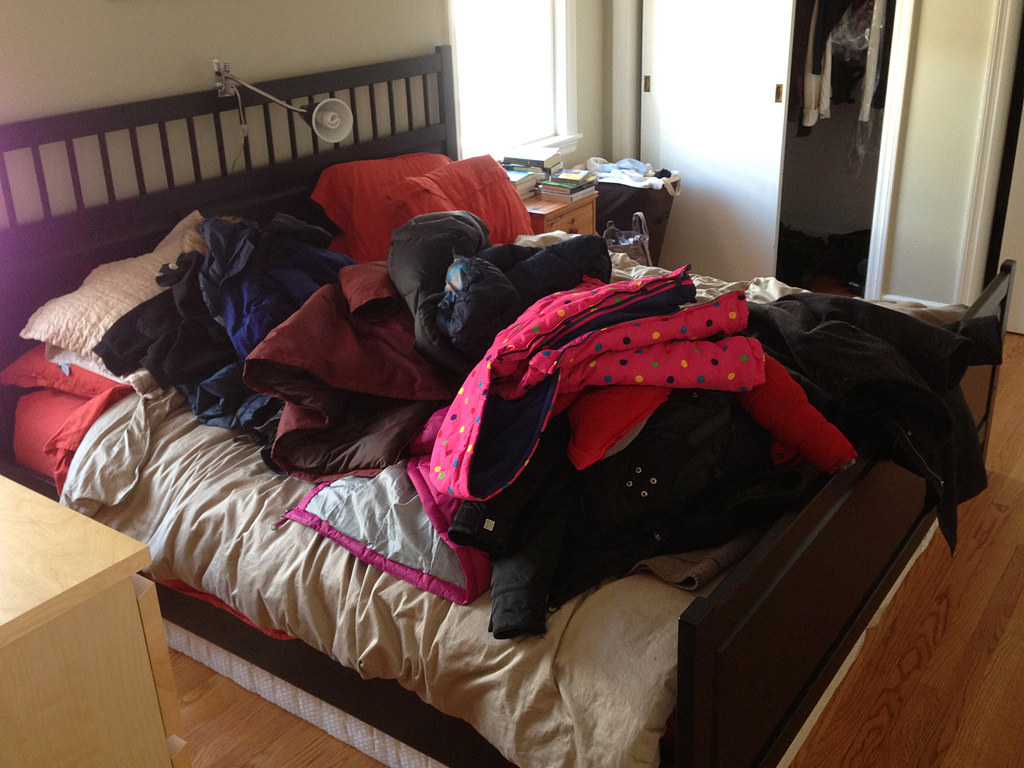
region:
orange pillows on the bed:
[321, 156, 522, 215]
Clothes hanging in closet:
[759, 8, 922, 215]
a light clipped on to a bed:
[202, 46, 367, 146]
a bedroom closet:
[717, 0, 923, 296]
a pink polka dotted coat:
[405, 258, 776, 489]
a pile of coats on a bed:
[122, 201, 1011, 654]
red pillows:
[318, 143, 528, 243]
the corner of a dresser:
[0, 512, 190, 757]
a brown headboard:
[12, 86, 215, 201]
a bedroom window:
[422, 1, 577, 156]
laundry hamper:
[566, 141, 697, 241]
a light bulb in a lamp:
[299, 90, 357, 142]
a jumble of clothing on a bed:
[111, 141, 854, 568]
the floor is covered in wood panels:
[915, 571, 989, 728]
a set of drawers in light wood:
[5, 488, 201, 767]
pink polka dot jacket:
[411, 266, 778, 498]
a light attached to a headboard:
[206, 56, 362, 168]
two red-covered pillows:
[315, 154, 543, 254]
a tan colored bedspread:
[157, 459, 274, 549]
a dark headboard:
[11, 51, 473, 244]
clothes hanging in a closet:
[804, 5, 880, 168]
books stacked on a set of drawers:
[532, 171, 603, 213]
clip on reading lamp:
[187, 39, 364, 154]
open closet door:
[642, 4, 886, 290]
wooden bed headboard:
[2, 51, 465, 247]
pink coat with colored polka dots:
[410, 225, 781, 523]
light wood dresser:
[0, 443, 198, 760]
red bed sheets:
[0, 302, 122, 462]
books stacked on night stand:
[468, 106, 595, 206]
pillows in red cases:
[310, 125, 533, 247]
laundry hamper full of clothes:
[574, 111, 677, 263]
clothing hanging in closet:
[786, 0, 898, 157]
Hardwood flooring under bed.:
[846, 571, 1003, 767]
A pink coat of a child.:
[426, 274, 803, 506]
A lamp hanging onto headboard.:
[189, 59, 367, 154]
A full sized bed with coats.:
[12, 30, 970, 759]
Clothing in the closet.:
[784, 11, 883, 221]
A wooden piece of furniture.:
[8, 507, 209, 761]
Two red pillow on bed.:
[322, 149, 637, 225]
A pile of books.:
[452, 4, 599, 239]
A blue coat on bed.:
[214, 217, 300, 348]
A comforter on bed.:
[179, 561, 647, 767]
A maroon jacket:
[242, 253, 476, 473]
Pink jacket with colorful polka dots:
[422, 271, 789, 531]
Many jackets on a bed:
[129, 158, 882, 687]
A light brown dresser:
[18, 459, 218, 732]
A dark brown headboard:
[52, 51, 467, 228]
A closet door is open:
[692, 4, 934, 314]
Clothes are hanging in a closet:
[770, 18, 925, 184]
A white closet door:
[629, 8, 800, 228]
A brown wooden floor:
[910, 595, 1003, 751]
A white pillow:
[49, 219, 243, 371]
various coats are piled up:
[119, 266, 869, 500]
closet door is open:
[675, 14, 945, 231]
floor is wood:
[901, 531, 1009, 751]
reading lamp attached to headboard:
[0, 45, 435, 257]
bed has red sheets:
[28, 330, 109, 457]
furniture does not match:
[16, 142, 609, 724]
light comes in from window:
[442, 10, 604, 122]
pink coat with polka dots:
[477, 300, 725, 428]